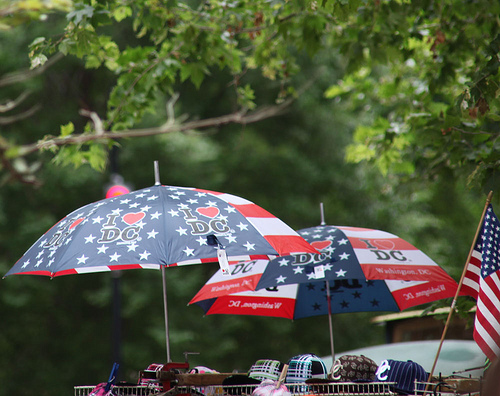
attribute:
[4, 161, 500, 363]
items — patriotic, love dc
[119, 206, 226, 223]
hearts — red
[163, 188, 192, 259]
stars — white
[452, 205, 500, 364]
flag — usa, on right, american, united states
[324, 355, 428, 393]
hats — dc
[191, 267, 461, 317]
umbrella border — washington dc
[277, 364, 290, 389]
clothes pin — plastic, blue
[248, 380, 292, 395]
hat — green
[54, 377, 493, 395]
sale cart — umbrella anchored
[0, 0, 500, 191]
trees — green, lush, overhead, in background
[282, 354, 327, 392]
hat — blue, white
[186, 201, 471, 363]
umbrella — middle, on right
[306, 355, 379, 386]
hat — brown, white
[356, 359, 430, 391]
hat — blue, striped, white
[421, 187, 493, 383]
stick — wooden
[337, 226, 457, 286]
stripes — red, white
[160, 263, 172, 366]
pole — silver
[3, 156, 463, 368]
umbrellas — i love dc, red, blue, white, open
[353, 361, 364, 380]
print — dc, brown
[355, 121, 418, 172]
leaves — green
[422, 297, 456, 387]
handle — brown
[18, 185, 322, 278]
item — patriotic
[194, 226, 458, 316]
item — patriotic